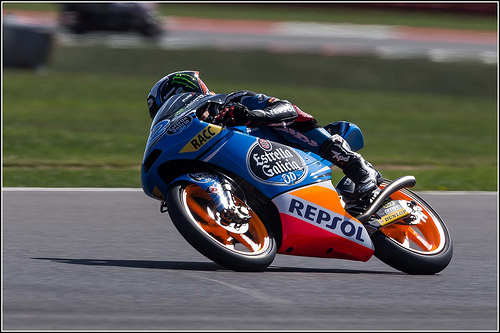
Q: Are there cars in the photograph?
A: No, there are no cars.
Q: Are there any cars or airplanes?
A: No, there are no cars or airplanes.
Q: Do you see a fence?
A: No, there are no fences.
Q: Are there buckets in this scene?
A: No, there are no buckets.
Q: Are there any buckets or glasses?
A: No, there are no buckets or glasses.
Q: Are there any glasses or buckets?
A: No, there are no buckets or glasses.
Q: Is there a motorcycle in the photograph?
A: Yes, there is a motorcycle.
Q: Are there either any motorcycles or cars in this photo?
A: Yes, there is a motorcycle.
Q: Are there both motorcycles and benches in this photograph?
A: No, there is a motorcycle but no benches.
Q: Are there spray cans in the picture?
A: No, there are no spray cans.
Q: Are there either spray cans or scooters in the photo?
A: No, there are no spray cans or scooters.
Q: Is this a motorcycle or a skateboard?
A: This is a motorcycle.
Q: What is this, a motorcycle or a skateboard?
A: This is a motorcycle.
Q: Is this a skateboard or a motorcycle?
A: This is a motorcycle.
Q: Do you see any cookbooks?
A: No, there are no cookbooks.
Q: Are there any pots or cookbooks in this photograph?
A: No, there are no cookbooks or pots.